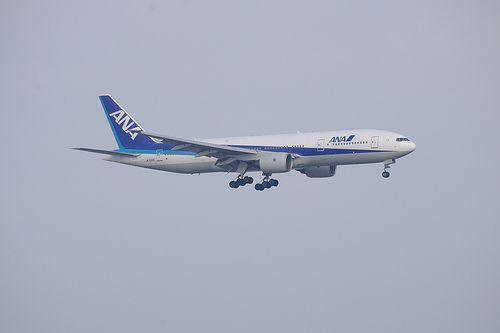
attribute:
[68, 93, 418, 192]
plane — blue, white, landing, flying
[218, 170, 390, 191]
landing gear — down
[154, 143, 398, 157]
stripe — dark, light blue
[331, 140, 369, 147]
windows — small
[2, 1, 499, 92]
sky — hazy, cloudy, dark, blue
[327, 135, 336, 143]
letter — blue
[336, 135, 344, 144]
letter — blue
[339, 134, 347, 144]
letter — blue